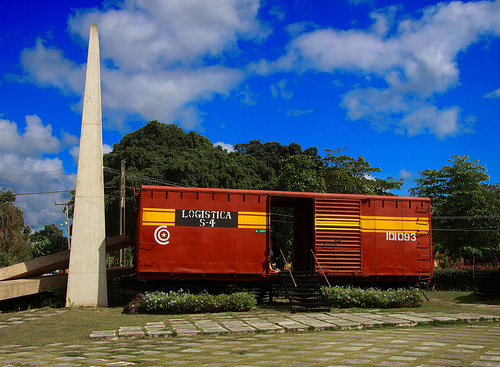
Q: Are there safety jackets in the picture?
A: No, there are no safety jackets.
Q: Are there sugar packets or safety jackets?
A: No, there are no safety jackets or sugar packets.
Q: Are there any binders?
A: No, there are no binders.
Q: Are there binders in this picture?
A: No, there are no binders.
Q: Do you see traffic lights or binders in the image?
A: No, there are no binders or traffic lights.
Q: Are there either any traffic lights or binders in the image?
A: No, there are no binders or traffic lights.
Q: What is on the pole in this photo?
A: The wires are on the pole.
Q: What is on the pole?
A: The wires are on the pole.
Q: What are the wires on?
A: The wires are on the pole.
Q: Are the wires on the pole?
A: Yes, the wires are on the pole.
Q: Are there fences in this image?
A: No, there are no fences.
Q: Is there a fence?
A: No, there are no fences.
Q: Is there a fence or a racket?
A: No, there are no fences or rackets.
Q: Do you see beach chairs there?
A: No, there are no beach chairs.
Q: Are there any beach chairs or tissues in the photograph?
A: No, there are no beach chairs or tissues.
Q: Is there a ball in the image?
A: No, there are no balls.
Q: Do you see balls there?
A: No, there are no balls.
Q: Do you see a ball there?
A: No, there are no balls.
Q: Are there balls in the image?
A: No, there are no balls.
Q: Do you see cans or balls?
A: No, there are no balls or cans.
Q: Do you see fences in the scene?
A: No, there are no fences.